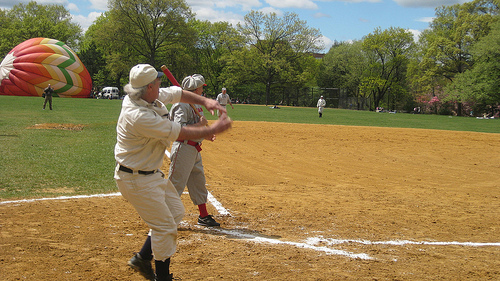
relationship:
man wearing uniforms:
[112, 63, 231, 281] [113, 99, 223, 251]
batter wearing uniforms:
[154, 73, 220, 228] [113, 99, 223, 251]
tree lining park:
[318, 24, 421, 104] [1, 6, 472, 256]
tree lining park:
[435, 26, 473, 92] [1, 6, 472, 256]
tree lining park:
[248, 30, 288, 94] [1, 6, 472, 256]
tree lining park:
[110, 9, 176, 71] [1, 6, 472, 256]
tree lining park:
[318, 55, 362, 105] [1, 6, 472, 256]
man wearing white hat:
[108, 58, 230, 280] [122, 61, 161, 91]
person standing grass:
[314, 95, 327, 118] [1, 93, 499, 206]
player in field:
[37, 80, 59, 114] [1, 88, 496, 276]